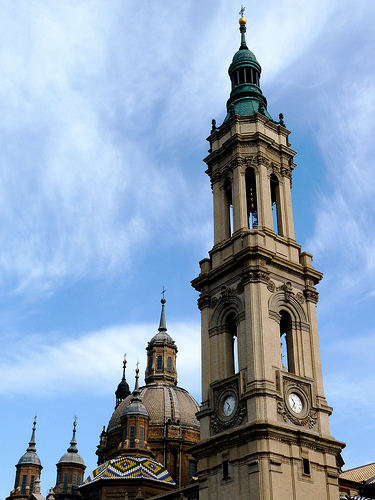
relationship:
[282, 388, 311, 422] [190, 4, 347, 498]
clock face on tower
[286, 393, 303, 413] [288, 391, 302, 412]
roman numerals on clock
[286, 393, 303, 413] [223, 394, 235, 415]
roman numerals on clock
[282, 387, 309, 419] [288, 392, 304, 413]
6:55 on clock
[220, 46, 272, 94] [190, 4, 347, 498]
green turret on tower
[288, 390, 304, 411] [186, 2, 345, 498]
clock on church tower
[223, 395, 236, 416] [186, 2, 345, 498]
clock on church tower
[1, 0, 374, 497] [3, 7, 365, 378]
clouds in blue sky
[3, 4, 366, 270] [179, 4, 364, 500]
sky above large cathedral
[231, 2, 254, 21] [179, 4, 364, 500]
cross on large cathedral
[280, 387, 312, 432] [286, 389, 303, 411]
10:35 on clock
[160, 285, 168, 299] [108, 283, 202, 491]
cross on steeple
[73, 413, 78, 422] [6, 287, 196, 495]
cross on several steeples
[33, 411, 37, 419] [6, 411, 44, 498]
cross on steeple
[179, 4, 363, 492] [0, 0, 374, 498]
large cathedral under sky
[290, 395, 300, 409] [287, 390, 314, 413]
clock hands on clock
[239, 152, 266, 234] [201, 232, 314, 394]
archway on tower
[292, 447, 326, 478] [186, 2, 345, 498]
small window on church tower